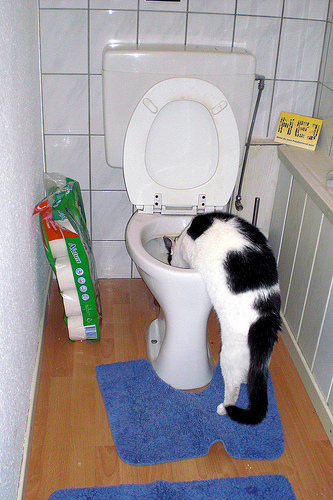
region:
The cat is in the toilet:
[146, 211, 243, 288]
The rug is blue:
[113, 407, 176, 448]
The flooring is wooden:
[57, 429, 115, 482]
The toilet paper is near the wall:
[37, 210, 133, 369]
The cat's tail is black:
[224, 362, 282, 438]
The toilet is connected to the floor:
[142, 317, 227, 418]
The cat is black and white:
[197, 218, 254, 310]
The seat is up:
[119, 64, 266, 210]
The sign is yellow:
[265, 96, 331, 149]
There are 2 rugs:
[177, 428, 241, 498]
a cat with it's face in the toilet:
[162, 209, 279, 425]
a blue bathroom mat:
[95, 357, 287, 463]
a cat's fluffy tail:
[226, 315, 280, 424]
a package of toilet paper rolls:
[33, 170, 110, 343]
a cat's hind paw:
[215, 402, 234, 418]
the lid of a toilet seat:
[122, 76, 240, 214]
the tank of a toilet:
[100, 40, 255, 170]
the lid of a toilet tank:
[101, 42, 259, 75]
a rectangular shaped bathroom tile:
[38, 8, 89, 76]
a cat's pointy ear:
[162, 233, 174, 248]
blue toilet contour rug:
[92, 356, 286, 467]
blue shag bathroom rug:
[47, 472, 298, 499]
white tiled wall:
[39, 0, 325, 279]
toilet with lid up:
[100, 41, 256, 391]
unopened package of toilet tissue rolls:
[30, 169, 102, 342]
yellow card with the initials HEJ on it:
[271, 109, 323, 152]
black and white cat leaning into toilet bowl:
[160, 210, 283, 427]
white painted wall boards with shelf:
[264, 142, 332, 446]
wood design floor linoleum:
[21, 275, 331, 499]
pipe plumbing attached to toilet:
[233, 72, 267, 211]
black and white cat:
[158, 209, 296, 431]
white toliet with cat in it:
[94, 42, 278, 429]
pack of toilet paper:
[39, 166, 110, 354]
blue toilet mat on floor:
[90, 345, 296, 470]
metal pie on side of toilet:
[230, 67, 272, 211]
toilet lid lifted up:
[121, 79, 239, 210]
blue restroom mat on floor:
[46, 469, 302, 498]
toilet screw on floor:
[147, 329, 159, 348]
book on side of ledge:
[268, 105, 325, 155]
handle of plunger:
[243, 195, 264, 225]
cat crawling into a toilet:
[124, 193, 262, 315]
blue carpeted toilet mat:
[84, 333, 299, 473]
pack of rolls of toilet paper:
[35, 165, 107, 335]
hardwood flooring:
[27, 340, 102, 471]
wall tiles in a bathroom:
[40, 15, 100, 150]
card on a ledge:
[265, 103, 327, 159]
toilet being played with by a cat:
[89, 33, 295, 385]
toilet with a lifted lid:
[106, 56, 273, 307]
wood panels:
[287, 174, 332, 337]